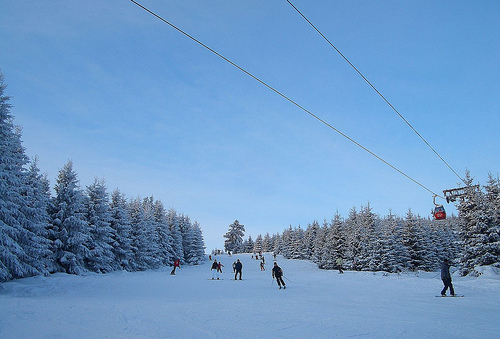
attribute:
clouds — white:
[3, 1, 499, 252]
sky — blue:
[1, 0, 500, 254]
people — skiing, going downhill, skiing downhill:
[169, 250, 464, 298]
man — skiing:
[270, 261, 288, 290]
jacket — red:
[174, 259, 181, 269]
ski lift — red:
[432, 191, 447, 222]